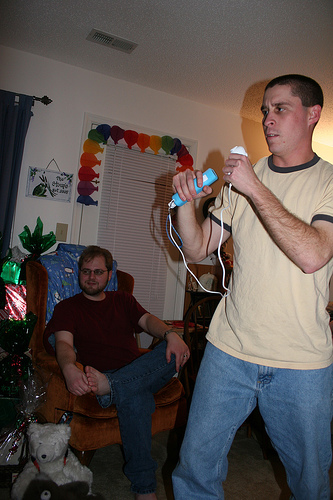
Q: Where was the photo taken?
A: In a house.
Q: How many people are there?
A: Two.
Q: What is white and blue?
A: Game controllers.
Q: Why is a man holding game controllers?
A: To play a video game.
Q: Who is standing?
A: One man.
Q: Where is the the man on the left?
A: On a chair.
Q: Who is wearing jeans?
A: Two men.